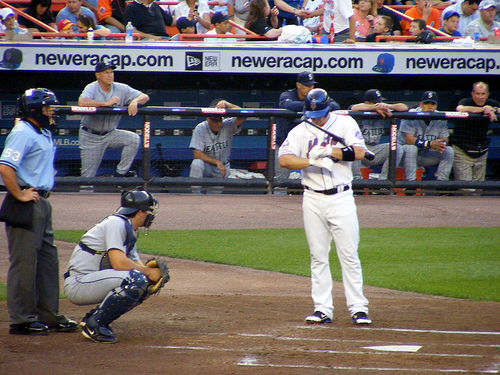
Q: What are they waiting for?
A: Man to fix glove.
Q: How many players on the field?
A: 3.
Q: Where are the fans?
A: In the bleachers.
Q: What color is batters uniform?
A: White.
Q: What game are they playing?
A: Baseball.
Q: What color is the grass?
A: Green.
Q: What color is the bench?
A: Blue.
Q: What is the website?
A: Neweracap.com.